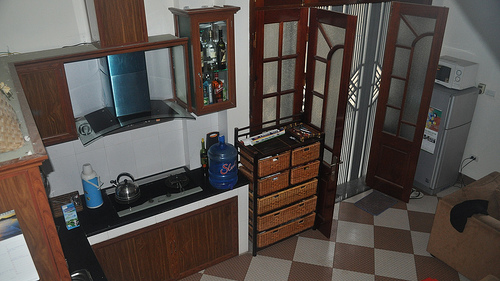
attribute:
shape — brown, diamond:
[203, 250, 254, 277]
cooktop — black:
[83, 147, 288, 252]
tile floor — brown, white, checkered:
[195, 188, 454, 278]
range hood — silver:
[75, 95, 197, 148]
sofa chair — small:
[426, 171, 498, 279]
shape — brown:
[300, 211, 341, 245]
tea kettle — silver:
[109, 169, 143, 202]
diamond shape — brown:
[372, 224, 414, 254]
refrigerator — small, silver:
[395, 58, 482, 222]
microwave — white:
[431, 51, 488, 106]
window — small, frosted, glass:
[266, 35, 295, 110]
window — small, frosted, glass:
[313, 31, 351, 163]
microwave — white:
[437, 51, 477, 93]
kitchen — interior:
[0, 1, 498, 279]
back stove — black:
[79, 164, 218, 241]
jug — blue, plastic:
[206, 135, 236, 187]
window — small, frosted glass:
[308, 94, 327, 127]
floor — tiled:
[181, 192, 481, 279]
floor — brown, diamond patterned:
[193, 170, 456, 279]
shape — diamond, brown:
[421, 254, 462, 279]